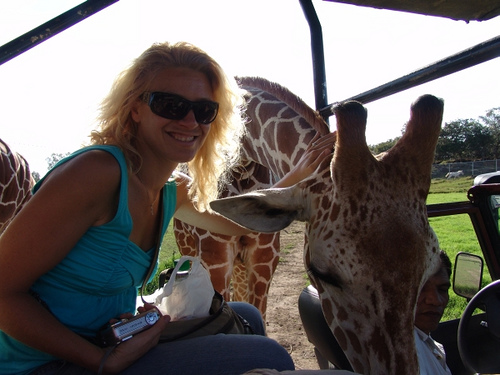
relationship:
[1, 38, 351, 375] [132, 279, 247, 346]
woman has bag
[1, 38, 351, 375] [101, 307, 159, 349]
woman holding camera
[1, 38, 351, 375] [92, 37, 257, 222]
woman has hair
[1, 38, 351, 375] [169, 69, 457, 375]
woman petting giraffe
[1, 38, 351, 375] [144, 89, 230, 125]
woman wearing sunglasses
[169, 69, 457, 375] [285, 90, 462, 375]
giraffe has head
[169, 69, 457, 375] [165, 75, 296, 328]
giraffe has body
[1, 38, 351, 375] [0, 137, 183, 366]
woman wearing shirt